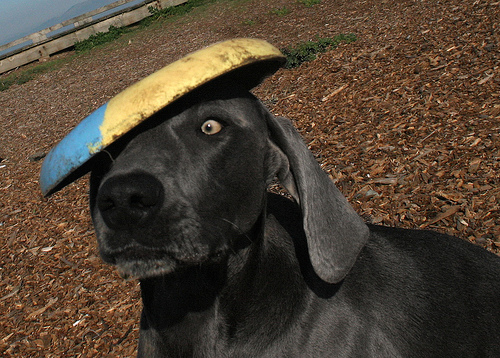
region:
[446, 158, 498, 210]
Small brown chips of wood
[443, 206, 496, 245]
Small brown chips of wood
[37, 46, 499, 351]
Black dog with frisbee on his head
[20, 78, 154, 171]
Blue and yellow frisbee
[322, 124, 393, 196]
Small brown chips of wood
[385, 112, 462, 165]
Small brown chips of wood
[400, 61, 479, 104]
Small brown chips of wood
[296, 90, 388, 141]
Small brown chips of wood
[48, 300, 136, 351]
Small brown chips of wood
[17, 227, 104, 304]
Small brown chips of wood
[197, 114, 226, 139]
eye of a dog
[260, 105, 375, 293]
ear of a dog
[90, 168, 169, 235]
nose of a dog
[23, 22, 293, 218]
blue and yellow frisbee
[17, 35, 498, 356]
dog with frisbee on head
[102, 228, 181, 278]
mouth of a dog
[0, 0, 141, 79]
concrete railing behind dog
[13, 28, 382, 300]
head of a dog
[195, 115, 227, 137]
the dog's eye is yellowish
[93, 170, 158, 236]
black nose on a dog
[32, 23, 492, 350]
The dog looks surprised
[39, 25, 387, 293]
This is a funny dog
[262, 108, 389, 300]
The dog has long ears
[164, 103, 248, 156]
The dog is wide eyed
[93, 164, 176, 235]
The dog's nose is very black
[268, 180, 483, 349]
The dog has a shiny coat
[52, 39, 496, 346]
The dog is dark black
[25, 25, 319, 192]
The dog is wearing a bowl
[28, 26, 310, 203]
The bowl is yellow and blue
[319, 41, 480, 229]
The ground is wood chip covered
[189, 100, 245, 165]
the eye of a dog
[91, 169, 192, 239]
the nose of a dog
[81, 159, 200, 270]
a dog with a black nose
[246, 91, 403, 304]
the ear of a dog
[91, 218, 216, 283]
the mouth of a dog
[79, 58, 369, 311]
the head of a dog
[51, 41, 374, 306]
a dog with a black head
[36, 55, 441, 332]
a black dog in a field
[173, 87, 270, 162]
one eye of a black dog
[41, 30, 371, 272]
a dog with a frisbee on it's head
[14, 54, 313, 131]
Yellow and blue frisbee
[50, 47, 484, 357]
Black dog with frisbee on head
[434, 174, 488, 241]
Patch of brown wood chips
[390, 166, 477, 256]
Patch of brown wood chips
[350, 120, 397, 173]
Patch of brown wood chips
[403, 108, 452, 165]
Patch of brown wood chips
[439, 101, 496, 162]
Patch of brown wood chips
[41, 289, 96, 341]
Patch of brown wood chips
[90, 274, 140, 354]
Patch of brown wood chips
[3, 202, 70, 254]
Patch of brown wood chips